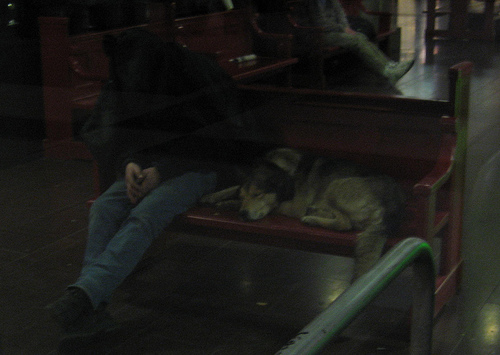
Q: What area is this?
A: A station.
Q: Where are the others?
A: Behind them.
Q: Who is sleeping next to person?
A: A dog.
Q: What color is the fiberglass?
A: Red.